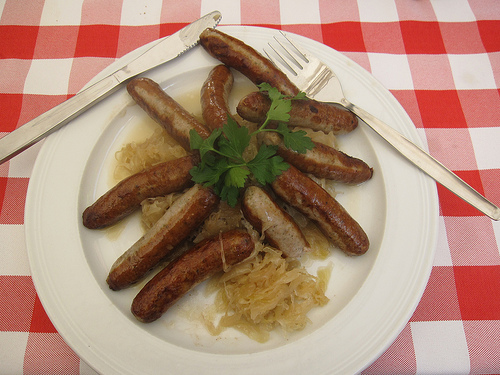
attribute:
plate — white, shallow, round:
[23, 24, 439, 374]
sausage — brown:
[127, 75, 209, 152]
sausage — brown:
[200, 64, 239, 129]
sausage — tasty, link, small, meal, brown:
[199, 28, 302, 98]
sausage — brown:
[237, 93, 359, 132]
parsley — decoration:
[187, 83, 310, 209]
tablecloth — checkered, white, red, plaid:
[1, 1, 499, 373]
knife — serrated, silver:
[0, 10, 221, 164]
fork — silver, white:
[262, 31, 499, 220]